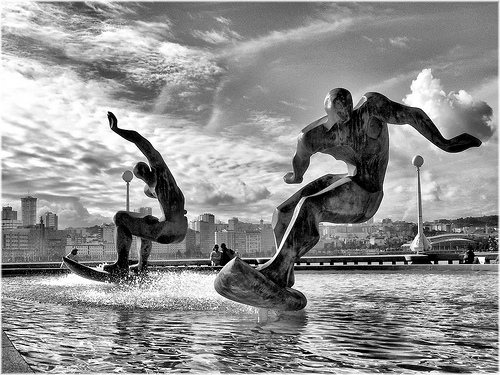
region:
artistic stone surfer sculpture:
[217, 82, 485, 320]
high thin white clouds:
[115, 26, 325, 97]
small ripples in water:
[325, 285, 481, 353]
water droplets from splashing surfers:
[62, 252, 216, 314]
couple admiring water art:
[206, 240, 240, 271]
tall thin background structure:
[405, 154, 432, 264]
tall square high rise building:
[13, 192, 44, 268]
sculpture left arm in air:
[100, 105, 173, 197]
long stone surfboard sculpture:
[207, 252, 313, 324]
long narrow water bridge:
[302, 252, 492, 269]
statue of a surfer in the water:
[50, 108, 192, 286]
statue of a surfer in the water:
[192, 68, 477, 323]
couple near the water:
[196, 232, 244, 271]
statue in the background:
[397, 148, 436, 260]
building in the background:
[17, 186, 43, 228]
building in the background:
[40, 203, 59, 234]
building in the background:
[191, 207, 218, 262]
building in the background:
[0, 201, 23, 229]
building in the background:
[205, 221, 275, 261]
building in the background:
[402, 226, 479, 265]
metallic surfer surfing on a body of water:
[194, 50, 414, 310]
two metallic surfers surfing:
[54, 20, 426, 327]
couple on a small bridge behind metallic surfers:
[186, 216, 246, 285]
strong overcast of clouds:
[58, 23, 360, 257]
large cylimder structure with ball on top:
[393, 144, 455, 252]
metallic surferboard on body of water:
[205, 237, 320, 328]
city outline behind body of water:
[9, 178, 460, 273]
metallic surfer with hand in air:
[28, 78, 193, 315]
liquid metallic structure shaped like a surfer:
[243, 62, 442, 329]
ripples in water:
[275, 301, 467, 351]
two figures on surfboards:
[93, 93, 433, 326]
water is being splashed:
[79, 251, 256, 365]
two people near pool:
[200, 240, 242, 278]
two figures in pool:
[91, 123, 387, 317]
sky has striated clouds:
[25, 42, 252, 197]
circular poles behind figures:
[407, 143, 448, 248]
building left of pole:
[6, 191, 103, 292]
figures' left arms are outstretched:
[102, 108, 481, 297]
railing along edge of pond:
[155, 248, 464, 303]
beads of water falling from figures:
[144, 258, 233, 322]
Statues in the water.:
[48, 87, 443, 356]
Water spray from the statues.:
[93, 245, 243, 317]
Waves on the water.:
[147, 277, 310, 351]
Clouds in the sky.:
[153, 72, 308, 197]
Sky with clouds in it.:
[111, 70, 303, 219]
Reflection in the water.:
[292, 272, 429, 373]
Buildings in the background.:
[171, 180, 357, 282]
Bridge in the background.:
[382, 171, 462, 256]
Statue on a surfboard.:
[204, 71, 392, 365]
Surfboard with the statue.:
[170, 222, 414, 355]